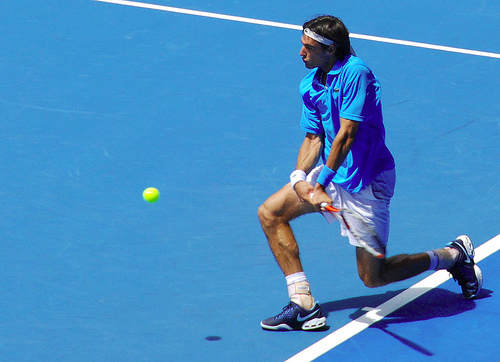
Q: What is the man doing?
A: Playing tennis.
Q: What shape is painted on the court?
A: Line.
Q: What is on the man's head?
A: Sweatband.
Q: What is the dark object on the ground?
A: Shadow.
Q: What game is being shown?
A: Tennis.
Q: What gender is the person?
A: Male.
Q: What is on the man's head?
A: Sweatband.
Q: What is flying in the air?
A: Ball.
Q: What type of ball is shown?
A: Tennis ball.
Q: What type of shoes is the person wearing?
A: Sneakers.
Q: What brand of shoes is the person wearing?
A: Nike.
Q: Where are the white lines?
A: On the tennis court.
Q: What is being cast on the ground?
A: Shadows.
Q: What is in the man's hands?
A: Racket.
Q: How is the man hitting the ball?
A: Swinging a racket.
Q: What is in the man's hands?
A: Tennis racket.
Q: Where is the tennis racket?
A: Player's hands.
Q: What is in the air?
A: Ball.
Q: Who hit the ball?
A: Man.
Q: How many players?
A: One.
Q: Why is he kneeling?
A: Hitting the ball.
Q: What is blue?
A: Court.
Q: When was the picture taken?
A: Daytime.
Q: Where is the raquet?
A: In his hand.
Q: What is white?
A: Lines.